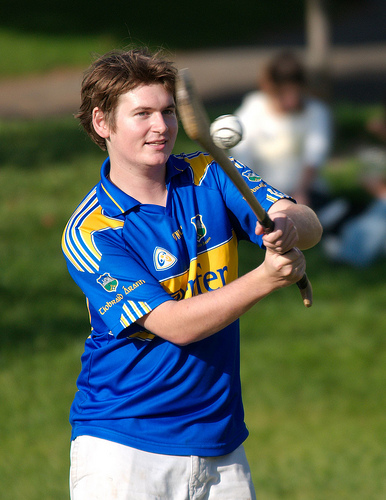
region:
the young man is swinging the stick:
[0, 49, 330, 314]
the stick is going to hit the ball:
[146, 60, 315, 309]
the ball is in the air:
[202, 87, 267, 175]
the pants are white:
[41, 416, 258, 494]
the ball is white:
[170, 93, 260, 167]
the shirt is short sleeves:
[15, 125, 326, 492]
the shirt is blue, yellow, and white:
[9, 126, 332, 456]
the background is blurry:
[6, 17, 381, 308]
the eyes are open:
[113, 94, 186, 124]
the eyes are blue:
[116, 90, 182, 128]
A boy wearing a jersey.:
[72, 23, 321, 460]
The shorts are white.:
[53, 390, 265, 497]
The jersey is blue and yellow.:
[55, 151, 285, 458]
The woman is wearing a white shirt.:
[236, 60, 344, 215]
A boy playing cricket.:
[72, 44, 313, 404]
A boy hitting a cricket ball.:
[61, 39, 340, 348]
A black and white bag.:
[307, 178, 367, 238]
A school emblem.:
[82, 251, 148, 315]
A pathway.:
[22, 29, 372, 115]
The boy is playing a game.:
[50, 41, 335, 363]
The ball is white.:
[209, 114, 244, 145]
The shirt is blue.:
[55, 189, 289, 459]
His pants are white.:
[58, 437, 262, 497]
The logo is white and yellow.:
[149, 242, 179, 269]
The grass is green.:
[264, 295, 361, 497]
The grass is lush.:
[231, 295, 384, 496]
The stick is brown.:
[163, 81, 320, 305]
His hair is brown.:
[56, 49, 161, 133]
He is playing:
[57, 56, 309, 432]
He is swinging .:
[98, 49, 336, 314]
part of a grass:
[321, 402, 340, 413]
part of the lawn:
[294, 399, 302, 411]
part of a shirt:
[145, 417, 159, 434]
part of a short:
[119, 487, 126, 492]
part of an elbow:
[171, 333, 174, 344]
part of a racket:
[299, 286, 303, 294]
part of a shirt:
[119, 313, 126, 323]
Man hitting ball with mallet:
[176, 63, 321, 310]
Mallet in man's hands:
[175, 68, 318, 307]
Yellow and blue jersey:
[55, 151, 295, 498]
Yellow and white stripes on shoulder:
[61, 187, 110, 273]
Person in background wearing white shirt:
[221, 50, 339, 209]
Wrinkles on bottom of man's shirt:
[69, 347, 254, 456]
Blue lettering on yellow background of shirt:
[127, 233, 238, 338]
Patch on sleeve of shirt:
[95, 271, 118, 291]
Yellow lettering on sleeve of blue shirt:
[98, 278, 145, 317]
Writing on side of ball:
[217, 134, 235, 145]